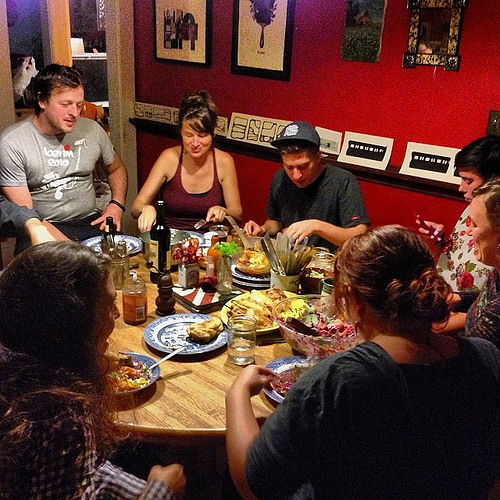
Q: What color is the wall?
A: Red.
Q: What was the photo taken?
A: At dinner.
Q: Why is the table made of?
A: Wood.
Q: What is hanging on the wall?
A: Pictures.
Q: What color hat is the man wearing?
A: Black.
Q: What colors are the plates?
A: Blue and white.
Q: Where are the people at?
A: In the dining room.